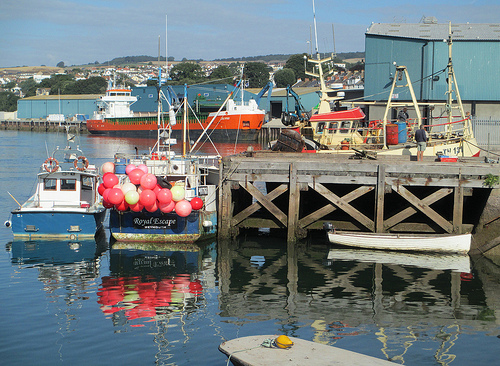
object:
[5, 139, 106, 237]
boat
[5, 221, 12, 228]
buoy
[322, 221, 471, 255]
boat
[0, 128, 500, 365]
water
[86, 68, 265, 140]
boat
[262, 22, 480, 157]
boat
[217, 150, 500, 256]
pier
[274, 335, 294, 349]
bouy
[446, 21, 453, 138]
mast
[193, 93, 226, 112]
engine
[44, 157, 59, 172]
innertube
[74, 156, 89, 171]
innertube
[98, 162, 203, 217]
balloons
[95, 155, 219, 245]
boat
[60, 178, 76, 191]
window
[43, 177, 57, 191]
window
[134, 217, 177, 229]
name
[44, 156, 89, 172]
life preserver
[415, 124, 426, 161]
person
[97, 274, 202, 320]
reflection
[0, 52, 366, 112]
trees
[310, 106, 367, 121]
roof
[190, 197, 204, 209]
balloon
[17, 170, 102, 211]
top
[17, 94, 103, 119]
building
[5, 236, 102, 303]
reflection